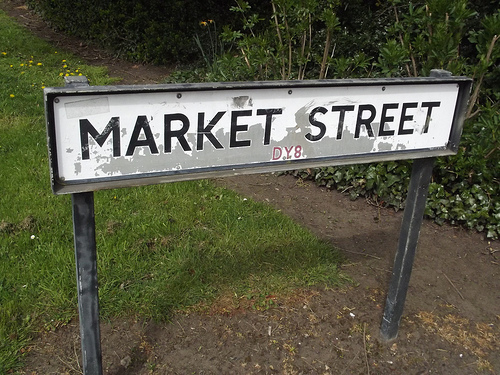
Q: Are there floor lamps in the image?
A: No, there are no floor lamps.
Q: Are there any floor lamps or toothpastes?
A: No, there are no floor lamps or toothpastes.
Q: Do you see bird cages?
A: No, there are no bird cages.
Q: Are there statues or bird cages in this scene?
A: No, there are no bird cages or statues.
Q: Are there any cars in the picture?
A: No, there are no cars.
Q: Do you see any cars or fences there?
A: No, there are no cars or fences.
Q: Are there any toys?
A: No, there are no toys.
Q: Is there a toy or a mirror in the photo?
A: No, there are no toys or mirrors.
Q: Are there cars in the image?
A: No, there are no cars.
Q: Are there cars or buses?
A: No, there are no cars or buses.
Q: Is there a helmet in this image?
A: No, there are no helmets.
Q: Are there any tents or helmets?
A: No, there are no helmets or tents.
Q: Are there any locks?
A: No, there are no locks.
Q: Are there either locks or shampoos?
A: No, there are no locks or shampoos.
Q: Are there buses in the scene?
A: No, there are no buses.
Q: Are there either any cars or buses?
A: No, there are no buses or cars.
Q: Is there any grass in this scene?
A: Yes, there is grass.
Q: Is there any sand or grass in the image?
A: Yes, there is grass.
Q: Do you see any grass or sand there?
A: Yes, there is grass.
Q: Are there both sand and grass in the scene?
A: No, there is grass but no sand.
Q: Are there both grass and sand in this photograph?
A: No, there is grass but no sand.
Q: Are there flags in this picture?
A: No, there are no flags.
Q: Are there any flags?
A: No, there are no flags.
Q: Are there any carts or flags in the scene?
A: No, there are no flags or carts.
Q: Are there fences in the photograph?
A: No, there are no fences.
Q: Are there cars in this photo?
A: No, there are no cars.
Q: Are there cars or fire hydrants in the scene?
A: No, there are no cars or fire hydrants.